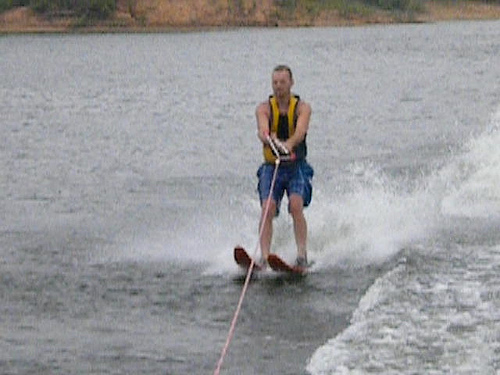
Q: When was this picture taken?
A: Daytime.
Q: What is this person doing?
A: Water skiing.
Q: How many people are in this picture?
A: 1.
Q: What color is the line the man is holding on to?
A: White.